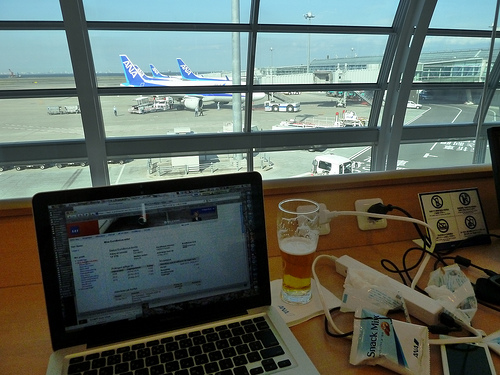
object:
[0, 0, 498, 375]
control tower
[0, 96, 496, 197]
tarmac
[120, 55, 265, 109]
plane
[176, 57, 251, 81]
plane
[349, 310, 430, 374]
snack pack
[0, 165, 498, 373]
desk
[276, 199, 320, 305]
glass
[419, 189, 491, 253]
sign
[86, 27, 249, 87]
window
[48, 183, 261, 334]
screen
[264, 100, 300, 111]
loading vehicle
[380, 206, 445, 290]
electrical cord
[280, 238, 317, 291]
beer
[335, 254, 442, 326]
surge protector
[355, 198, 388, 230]
outlet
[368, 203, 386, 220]
plug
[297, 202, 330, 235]
outlet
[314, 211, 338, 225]
plug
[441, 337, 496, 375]
cell phone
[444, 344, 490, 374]
touch screen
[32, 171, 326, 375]
computer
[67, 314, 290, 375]
keyboard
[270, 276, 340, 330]
napkin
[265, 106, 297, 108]
stripe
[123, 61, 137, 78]
logo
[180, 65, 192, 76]
logo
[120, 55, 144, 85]
tail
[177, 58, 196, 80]
tail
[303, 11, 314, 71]
light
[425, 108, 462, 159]
line